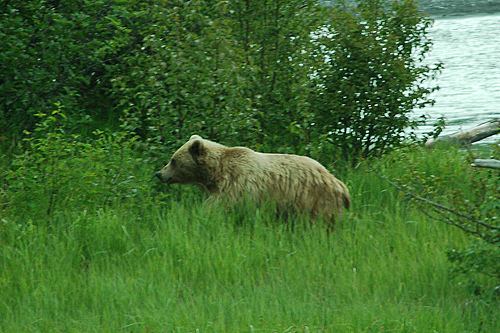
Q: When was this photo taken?
A: Daytime.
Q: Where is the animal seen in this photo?
A: In grass.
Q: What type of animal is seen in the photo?
A: Bear.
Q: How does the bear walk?
A: On four feet.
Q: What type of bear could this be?
A: Grizzly.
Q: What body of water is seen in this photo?
A: Lake.